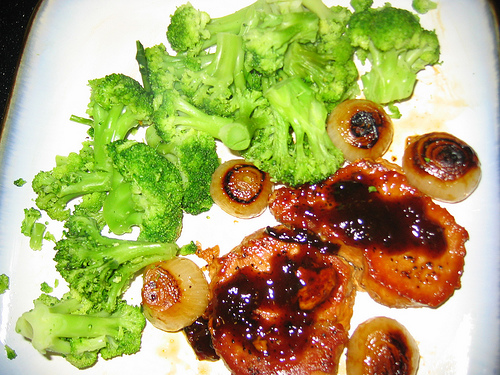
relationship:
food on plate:
[24, 7, 481, 373] [0, 1, 500, 373]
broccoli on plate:
[0, 2, 447, 368] [0, 1, 500, 373]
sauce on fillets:
[210, 245, 347, 375] [204, 223, 363, 374]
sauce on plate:
[182, 317, 223, 363] [0, 1, 500, 373]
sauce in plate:
[182, 317, 223, 363] [0, 1, 500, 373]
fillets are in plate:
[192, 223, 359, 373] [0, 1, 500, 373]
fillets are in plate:
[266, 154, 471, 309] [0, 1, 500, 373]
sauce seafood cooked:
[182, 317, 223, 363] [140, 207, 408, 375]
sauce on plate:
[162, 250, 262, 373] [0, 1, 500, 373]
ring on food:
[151, 277, 179, 325] [209, 158, 271, 219]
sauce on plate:
[182, 321, 219, 364] [55, 340, 145, 375]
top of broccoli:
[36, 169, 169, 341] [109, 133, 186, 244]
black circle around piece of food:
[208, 247, 307, 375] [72, 19, 479, 364]